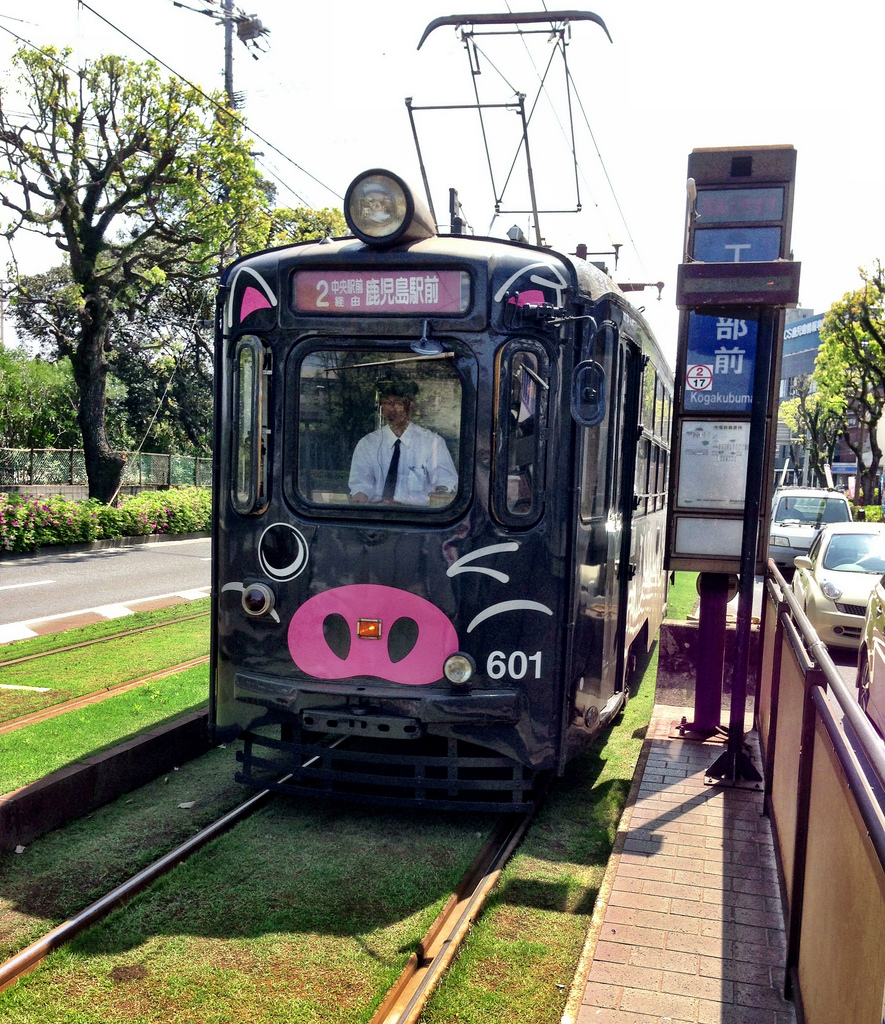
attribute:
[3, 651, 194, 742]
grass — trimmed, green, sunlit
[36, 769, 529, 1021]
grass — green, trimmed, short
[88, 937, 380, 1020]
ground — green, brown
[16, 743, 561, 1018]
tracks — train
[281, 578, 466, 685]
logo — pink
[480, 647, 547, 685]
numbers — white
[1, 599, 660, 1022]
grass — sparse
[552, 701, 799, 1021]
platform — brick, tiled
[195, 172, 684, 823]
train — black, shiny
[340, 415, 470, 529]
shirt — white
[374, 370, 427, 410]
hat — black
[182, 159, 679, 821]
train car — black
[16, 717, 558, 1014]
tracks — train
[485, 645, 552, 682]
numbers — white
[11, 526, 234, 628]
road — black , paved 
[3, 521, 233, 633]
road — paved , black 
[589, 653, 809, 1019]
platform — brick